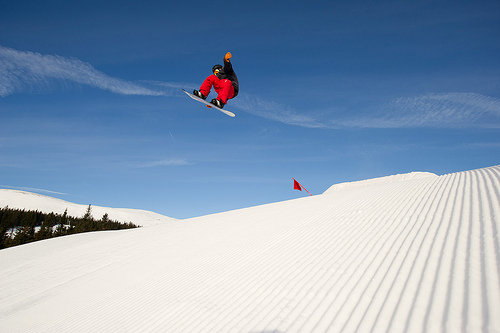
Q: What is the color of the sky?
A: Blue.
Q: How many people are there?
A: One.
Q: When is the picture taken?
A: Daytime.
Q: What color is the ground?
A: White.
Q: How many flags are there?
A: 1.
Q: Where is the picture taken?
A: In the snow.